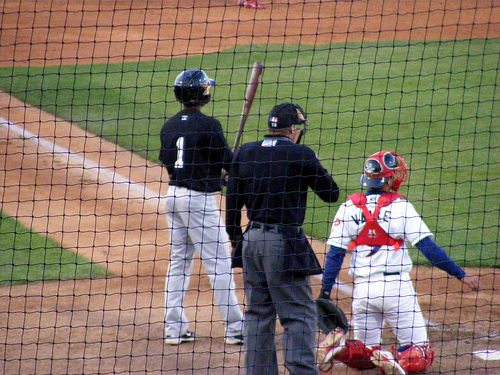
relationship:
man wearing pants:
[221, 96, 341, 372] [235, 219, 321, 373]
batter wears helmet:
[156, 67, 246, 347] [167, 66, 226, 112]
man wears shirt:
[224, 100, 340, 375] [219, 136, 344, 236]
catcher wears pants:
[319, 142, 485, 370] [343, 271, 435, 347]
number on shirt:
[170, 136, 185, 171] [153, 109, 231, 196]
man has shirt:
[221, 96, 341, 372] [219, 136, 344, 236]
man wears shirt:
[224, 100, 340, 375] [223, 134, 339, 247]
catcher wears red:
[319, 142, 485, 370] [341, 189, 406, 252]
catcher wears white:
[319, 142, 485, 370] [332, 193, 426, 345]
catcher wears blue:
[319, 142, 485, 370] [415, 238, 455, 272]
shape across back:
[347, 193, 401, 247] [343, 193, 412, 277]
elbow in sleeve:
[315, 180, 345, 205] [298, 147, 337, 203]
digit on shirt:
[169, 135, 187, 170] [152, 107, 232, 186]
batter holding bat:
[156, 67, 246, 347] [227, 60, 267, 148]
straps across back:
[347, 190, 400, 253] [336, 192, 410, 276]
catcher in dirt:
[313, 149, 481, 375] [6, 124, 484, 364]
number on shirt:
[170, 134, 188, 174] [158, 107, 233, 192]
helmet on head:
[172, 67, 212, 107] [172, 67, 217, 111]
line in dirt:
[4, 115, 162, 208] [1, 90, 484, 361]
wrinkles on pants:
[189, 211, 225, 271] [160, 183, 245, 329]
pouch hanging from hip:
[270, 224, 325, 281] [239, 220, 302, 243]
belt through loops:
[247, 221, 300, 231] [244, 220, 294, 232]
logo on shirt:
[258, 137, 278, 149] [223, 139, 337, 261]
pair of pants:
[242, 222, 331, 362] [232, 220, 318, 365]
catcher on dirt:
[313, 149, 481, 375] [7, 9, 497, 371]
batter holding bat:
[156, 67, 246, 347] [233, 58, 264, 149]